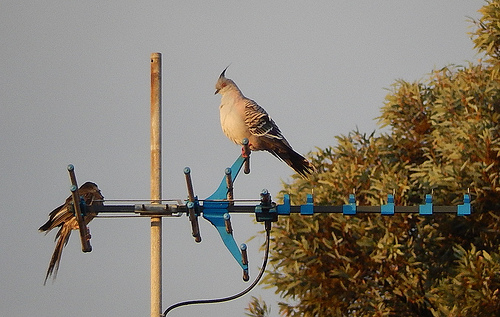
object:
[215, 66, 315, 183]
bird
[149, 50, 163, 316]
pole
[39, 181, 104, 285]
bird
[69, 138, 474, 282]
antenna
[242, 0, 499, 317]
tree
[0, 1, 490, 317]
sky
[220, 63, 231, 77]
feather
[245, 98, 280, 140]
wing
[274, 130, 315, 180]
tail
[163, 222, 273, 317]
cable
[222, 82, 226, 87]
eye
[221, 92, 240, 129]
chest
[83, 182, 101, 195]
head